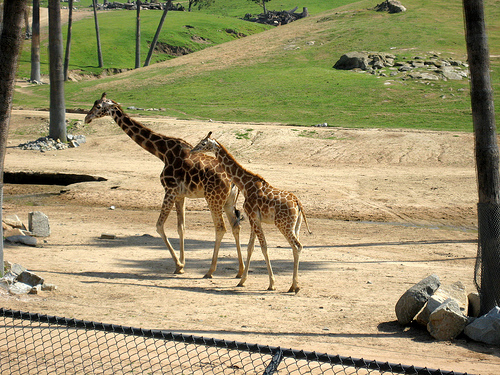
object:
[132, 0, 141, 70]
tree trunk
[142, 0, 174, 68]
tree trunk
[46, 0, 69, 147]
tree trunk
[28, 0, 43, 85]
tree trunk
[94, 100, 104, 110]
eye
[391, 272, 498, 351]
rocks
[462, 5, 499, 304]
tree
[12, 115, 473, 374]
bare land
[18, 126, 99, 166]
rocks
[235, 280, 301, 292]
hooves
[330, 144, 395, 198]
ground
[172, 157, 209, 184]
spots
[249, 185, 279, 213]
spots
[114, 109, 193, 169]
spots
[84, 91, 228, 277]
body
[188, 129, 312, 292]
body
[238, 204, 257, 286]
leg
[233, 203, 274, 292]
legs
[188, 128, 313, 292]
giraffe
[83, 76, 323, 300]
giraffes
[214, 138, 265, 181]
mane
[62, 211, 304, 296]
shadow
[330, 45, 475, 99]
large rock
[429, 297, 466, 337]
large rock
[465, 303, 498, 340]
large rock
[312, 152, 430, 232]
ground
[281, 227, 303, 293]
giraffe leg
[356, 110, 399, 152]
ground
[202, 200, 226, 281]
leg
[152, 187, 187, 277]
leg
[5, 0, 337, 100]
ravine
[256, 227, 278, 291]
giraffeleg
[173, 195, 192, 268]
giraffeleg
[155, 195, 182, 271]
giraffeleg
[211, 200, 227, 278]
giraffeleg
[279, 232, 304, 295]
giraffeleg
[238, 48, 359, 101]
grass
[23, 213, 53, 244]
rock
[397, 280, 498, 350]
rock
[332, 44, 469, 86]
rocks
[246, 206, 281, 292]
leg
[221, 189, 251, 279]
leg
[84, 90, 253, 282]
giraffe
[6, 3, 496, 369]
zoo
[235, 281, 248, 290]
hoof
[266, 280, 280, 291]
hoof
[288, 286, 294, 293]
hoof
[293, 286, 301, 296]
hoof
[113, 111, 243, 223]
hide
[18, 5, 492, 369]
earth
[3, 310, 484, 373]
fence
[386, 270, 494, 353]
cluster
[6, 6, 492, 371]
field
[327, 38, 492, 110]
cluster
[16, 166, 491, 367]
surface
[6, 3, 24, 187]
trunk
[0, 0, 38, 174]
tree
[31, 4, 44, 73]
trunk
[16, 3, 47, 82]
tree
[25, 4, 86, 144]
tree